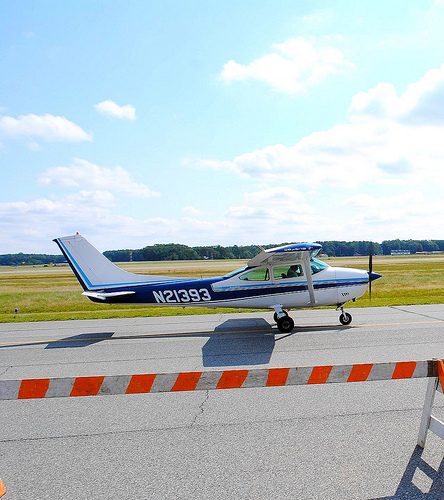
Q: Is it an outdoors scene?
A: Yes, it is outdoors.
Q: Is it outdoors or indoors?
A: It is outdoors.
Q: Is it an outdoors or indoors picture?
A: It is outdoors.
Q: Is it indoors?
A: No, it is outdoors.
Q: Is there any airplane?
A: Yes, there is an airplane.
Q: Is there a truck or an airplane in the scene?
A: Yes, there is an airplane.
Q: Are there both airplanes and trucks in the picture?
A: No, there is an airplane but no trucks.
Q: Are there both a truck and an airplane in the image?
A: No, there is an airplane but no trucks.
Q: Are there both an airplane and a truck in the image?
A: No, there is an airplane but no trucks.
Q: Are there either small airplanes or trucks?
A: Yes, there is a small airplane.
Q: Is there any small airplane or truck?
A: Yes, there is a small airplane.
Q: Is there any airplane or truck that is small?
A: Yes, the airplane is small.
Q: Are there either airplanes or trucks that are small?
A: Yes, the airplane is small.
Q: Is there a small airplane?
A: Yes, there is a small airplane.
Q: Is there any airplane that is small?
A: Yes, there is an airplane that is small.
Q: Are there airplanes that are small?
A: Yes, there is an airplane that is small.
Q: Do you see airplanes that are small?
A: Yes, there is an airplane that is small.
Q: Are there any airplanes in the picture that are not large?
A: Yes, there is a small airplane.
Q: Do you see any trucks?
A: No, there are no trucks.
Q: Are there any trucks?
A: No, there are no trucks.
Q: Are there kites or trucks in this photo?
A: No, there are no trucks or kites.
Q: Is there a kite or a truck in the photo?
A: No, there are no trucks or kites.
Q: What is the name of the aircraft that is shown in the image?
A: The aircraft is an airplane.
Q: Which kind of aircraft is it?
A: The aircraft is an airplane.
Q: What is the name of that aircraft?
A: That is an airplane.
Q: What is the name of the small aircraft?
A: The aircraft is an airplane.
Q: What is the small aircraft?
A: The aircraft is an airplane.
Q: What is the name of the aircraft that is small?
A: The aircraft is an airplane.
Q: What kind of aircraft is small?
A: The aircraft is an airplane.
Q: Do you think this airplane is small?
A: Yes, the airplane is small.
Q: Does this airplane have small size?
A: Yes, the airplane is small.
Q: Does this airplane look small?
A: Yes, the airplane is small.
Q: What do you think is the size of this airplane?
A: The airplane is small.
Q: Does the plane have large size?
A: No, the plane is small.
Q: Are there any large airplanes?
A: No, there is an airplane but it is small.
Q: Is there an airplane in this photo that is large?
A: No, there is an airplane but it is small.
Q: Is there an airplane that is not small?
A: No, there is an airplane but it is small.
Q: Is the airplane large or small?
A: The airplane is small.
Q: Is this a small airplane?
A: Yes, this is a small airplane.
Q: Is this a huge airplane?
A: No, this is a small airplane.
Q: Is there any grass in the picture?
A: Yes, there is grass.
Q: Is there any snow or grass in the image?
A: Yes, there is grass.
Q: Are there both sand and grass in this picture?
A: No, there is grass but no sand.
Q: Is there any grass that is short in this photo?
A: Yes, there is short grass.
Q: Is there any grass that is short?
A: Yes, there is grass that is short.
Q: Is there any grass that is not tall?
A: Yes, there is short grass.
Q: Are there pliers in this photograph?
A: No, there are no pliers.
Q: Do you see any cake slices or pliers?
A: No, there are no pliers or cake slices.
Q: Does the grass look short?
A: Yes, the grass is short.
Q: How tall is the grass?
A: The grass is short.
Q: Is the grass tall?
A: No, the grass is short.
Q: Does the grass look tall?
A: No, the grass is short.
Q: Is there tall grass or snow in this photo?
A: No, there is grass but it is short.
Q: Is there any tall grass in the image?
A: No, there is grass but it is short.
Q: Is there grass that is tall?
A: No, there is grass but it is short.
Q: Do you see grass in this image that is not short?
A: No, there is grass but it is short.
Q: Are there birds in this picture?
A: No, there are no birds.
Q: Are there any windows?
A: Yes, there is a window.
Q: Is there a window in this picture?
A: Yes, there is a window.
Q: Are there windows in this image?
A: Yes, there is a window.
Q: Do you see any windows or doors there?
A: Yes, there is a window.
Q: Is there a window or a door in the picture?
A: Yes, there is a window.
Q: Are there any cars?
A: No, there are no cars.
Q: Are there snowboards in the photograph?
A: No, there are no snowboards.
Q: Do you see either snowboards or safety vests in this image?
A: No, there are no snowboards or safety vests.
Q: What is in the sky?
A: The clouds are in the sky.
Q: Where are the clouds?
A: The clouds are in the sky.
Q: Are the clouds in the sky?
A: Yes, the clouds are in the sky.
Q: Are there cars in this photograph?
A: No, there are no cars.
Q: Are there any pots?
A: No, there are no pots.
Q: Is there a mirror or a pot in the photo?
A: No, there are no pots or mirrors.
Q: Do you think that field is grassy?
A: Yes, the field is grassy.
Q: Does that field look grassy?
A: Yes, the field is grassy.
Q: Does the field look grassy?
A: Yes, the field is grassy.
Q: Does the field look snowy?
A: No, the field is grassy.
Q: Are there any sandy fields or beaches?
A: No, there is a field but it is grassy.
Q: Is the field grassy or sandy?
A: The field is grassy.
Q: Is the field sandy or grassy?
A: The field is grassy.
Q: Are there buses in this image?
A: No, there are no buses.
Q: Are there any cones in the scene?
A: No, there are no cones.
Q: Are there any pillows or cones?
A: No, there are no cones or pillows.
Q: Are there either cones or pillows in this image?
A: No, there are no cones or pillows.